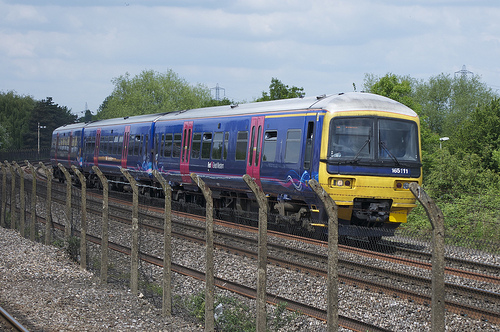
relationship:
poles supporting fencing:
[4, 162, 447, 327] [450, 245, 499, 332]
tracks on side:
[111, 205, 238, 251] [99, 202, 199, 246]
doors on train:
[246, 118, 260, 176] [52, 124, 413, 239]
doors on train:
[179, 125, 192, 185] [52, 124, 413, 239]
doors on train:
[121, 125, 129, 164] [52, 124, 413, 239]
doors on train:
[91, 131, 101, 162] [52, 124, 413, 239]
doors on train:
[67, 131, 74, 166] [52, 124, 413, 239]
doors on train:
[54, 136, 59, 163] [52, 124, 413, 239]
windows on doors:
[250, 122, 262, 165] [246, 118, 260, 176]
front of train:
[322, 104, 417, 225] [52, 124, 413, 239]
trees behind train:
[417, 97, 498, 219] [52, 124, 413, 239]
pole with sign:
[37, 126, 41, 157] [38, 120, 48, 130]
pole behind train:
[37, 126, 41, 157] [52, 124, 413, 239]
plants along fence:
[217, 297, 254, 332] [2, 174, 497, 327]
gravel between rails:
[5, 249, 119, 328] [1, 307, 21, 329]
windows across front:
[332, 120, 418, 165] [322, 104, 417, 225]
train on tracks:
[52, 124, 413, 239] [395, 237, 489, 289]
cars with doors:
[52, 128, 327, 178] [246, 118, 260, 176]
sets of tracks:
[396, 245, 495, 315] [111, 205, 238, 251]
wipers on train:
[355, 138, 399, 159] [52, 124, 413, 239]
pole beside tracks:
[37, 126, 41, 157] [111, 205, 238, 251]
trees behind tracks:
[417, 97, 498, 219] [111, 205, 238, 251]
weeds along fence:
[172, 289, 203, 326] [2, 174, 497, 327]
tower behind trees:
[452, 64, 473, 83] [417, 97, 498, 219]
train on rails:
[52, 124, 413, 239] [395, 237, 489, 289]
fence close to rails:
[2, 174, 497, 327] [1, 307, 21, 329]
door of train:
[246, 118, 260, 176] [52, 124, 413, 239]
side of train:
[55, 112, 321, 180] [52, 124, 413, 239]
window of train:
[59, 130, 301, 158] [52, 124, 413, 239]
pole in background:
[37, 126, 41, 157] [2, 0, 50, 145]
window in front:
[332, 120, 418, 165] [322, 104, 417, 225]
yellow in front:
[319, 111, 423, 225] [322, 104, 417, 225]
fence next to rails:
[2, 174, 497, 327] [1, 307, 24, 330]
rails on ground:
[1, 307, 24, 330] [5, 249, 119, 328]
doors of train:
[247, 118, 260, 176] [52, 124, 413, 239]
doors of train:
[179, 125, 192, 185] [52, 124, 413, 239]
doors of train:
[121, 125, 129, 164] [52, 124, 413, 239]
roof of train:
[48, 92, 418, 132] [52, 124, 413, 239]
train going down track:
[52, 124, 413, 239] [395, 237, 489, 289]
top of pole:
[208, 83, 235, 107] [216, 89, 221, 102]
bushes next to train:
[423, 160, 499, 224] [52, 124, 413, 239]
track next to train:
[216, 228, 265, 263] [52, 124, 413, 239]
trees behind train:
[4, 95, 36, 168] [52, 124, 413, 239]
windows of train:
[332, 120, 418, 165] [52, 124, 413, 239]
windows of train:
[194, 135, 227, 163] [52, 124, 413, 239]